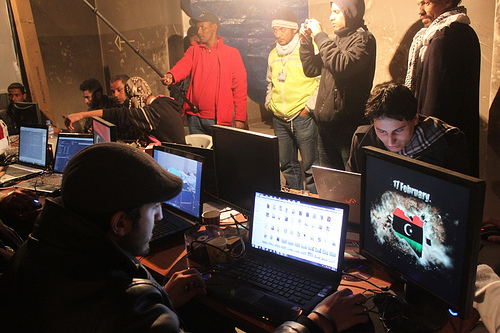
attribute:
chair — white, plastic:
[186, 131, 213, 150]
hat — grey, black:
[264, 9, 298, 33]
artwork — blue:
[188, 1, 311, 88]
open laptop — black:
[201, 169, 353, 324]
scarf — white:
[399, 4, 474, 93]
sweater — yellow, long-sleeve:
[308, 46, 395, 123]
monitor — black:
[346, 124, 497, 304]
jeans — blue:
[273, 117, 315, 192]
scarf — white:
[404, 4, 472, 84]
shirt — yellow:
[259, 42, 321, 114]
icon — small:
[264, 202, 271, 210]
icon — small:
[263, 211, 271, 219]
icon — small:
[282, 214, 291, 222]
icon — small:
[304, 209, 311, 219]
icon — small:
[316, 234, 324, 241]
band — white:
[268, 19, 300, 29]